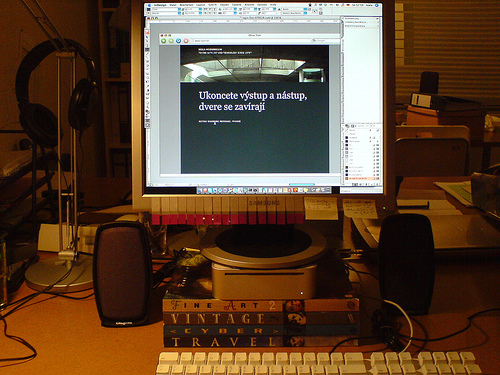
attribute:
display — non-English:
[181, 83, 328, 172]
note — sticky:
[306, 194, 341, 223]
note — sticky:
[343, 199, 380, 224]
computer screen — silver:
[126, 1, 398, 202]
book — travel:
[167, 329, 298, 348]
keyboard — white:
[142, 350, 489, 371]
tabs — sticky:
[141, 187, 320, 234]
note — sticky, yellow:
[341, 192, 381, 222]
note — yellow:
[300, 190, 341, 222]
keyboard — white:
[152, 348, 479, 374]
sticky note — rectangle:
[303, 192, 337, 222]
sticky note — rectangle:
[341, 195, 378, 219]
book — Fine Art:
[165, 295, 370, 317]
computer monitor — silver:
[127, 7, 393, 219]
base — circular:
[204, 227, 326, 264]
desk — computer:
[2, 166, 499, 373]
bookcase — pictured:
[87, 6, 128, 205]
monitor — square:
[103, 2, 484, 372]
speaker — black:
[380, 210, 438, 317]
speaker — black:
[88, 220, 159, 329]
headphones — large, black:
[6, 24, 109, 157]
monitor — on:
[98, 6, 404, 205]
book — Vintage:
[163, 312, 358, 324]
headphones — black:
[11, 37, 100, 147]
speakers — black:
[92, 212, 439, 329]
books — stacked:
[161, 248, 361, 349]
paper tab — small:
[150, 194, 162, 224]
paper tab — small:
[160, 195, 171, 222]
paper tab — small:
[177, 195, 187, 225]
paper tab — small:
[220, 194, 227, 225]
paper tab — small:
[257, 195, 266, 225]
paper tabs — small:
[150, 195, 305, 223]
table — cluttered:
[1, 250, 498, 372]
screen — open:
[130, 0, 385, 210]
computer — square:
[129, 2, 395, 226]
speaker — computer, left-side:
[88, 219, 152, 334]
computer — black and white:
[79, 19, 424, 199]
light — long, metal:
[57, 24, 145, 194]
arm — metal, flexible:
[15, 5, 83, 269]